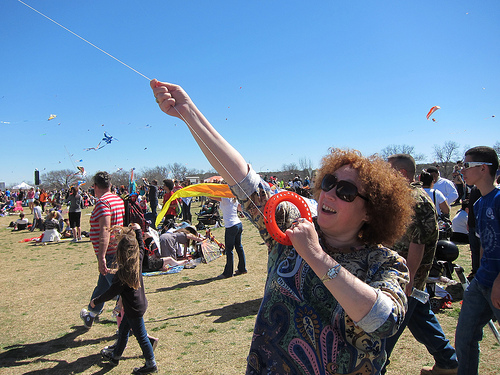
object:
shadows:
[0, 324, 147, 373]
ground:
[0, 202, 499, 374]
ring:
[290, 224, 298, 230]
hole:
[275, 201, 305, 233]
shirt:
[89, 190, 126, 254]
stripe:
[100, 193, 124, 200]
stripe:
[93, 209, 110, 215]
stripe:
[106, 217, 118, 224]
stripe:
[109, 208, 124, 217]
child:
[89, 222, 158, 374]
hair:
[387, 154, 416, 177]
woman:
[159, 227, 205, 261]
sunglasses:
[317, 173, 371, 203]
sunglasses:
[458, 160, 492, 169]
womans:
[418, 171, 451, 278]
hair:
[312, 145, 417, 248]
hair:
[464, 145, 499, 178]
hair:
[71, 186, 79, 194]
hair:
[92, 170, 111, 189]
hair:
[419, 171, 433, 188]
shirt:
[218, 192, 241, 229]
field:
[0, 0, 499, 374]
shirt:
[93, 228, 148, 316]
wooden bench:
[152, 177, 222, 232]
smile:
[316, 200, 352, 229]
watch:
[321, 262, 343, 283]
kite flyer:
[150, 77, 415, 374]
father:
[80, 171, 160, 357]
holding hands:
[98, 257, 120, 277]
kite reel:
[265, 190, 313, 246]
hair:
[105, 224, 143, 290]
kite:
[154, 182, 237, 230]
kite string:
[16, 0, 273, 223]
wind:
[70, 145, 101, 170]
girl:
[207, 183, 248, 278]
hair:
[163, 178, 175, 191]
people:
[62, 185, 87, 244]